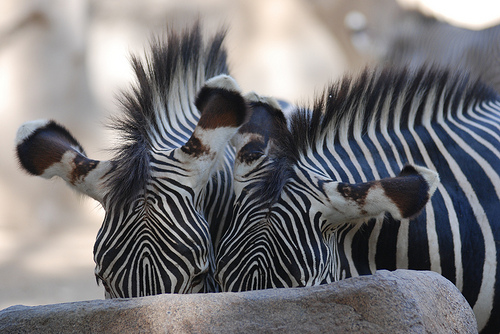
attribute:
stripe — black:
[166, 183, 190, 250]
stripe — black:
[396, 104, 459, 298]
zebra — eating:
[212, 52, 499, 332]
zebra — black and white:
[8, 20, 325, 298]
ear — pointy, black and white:
[347, 157, 454, 259]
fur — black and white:
[127, 21, 225, 167]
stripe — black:
[432, 89, 482, 317]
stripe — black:
[421, 85, 498, 296]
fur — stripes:
[368, 76, 498, 249]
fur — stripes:
[416, 111, 493, 274]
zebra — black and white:
[20, 28, 296, 306]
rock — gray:
[4, 271, 484, 329]